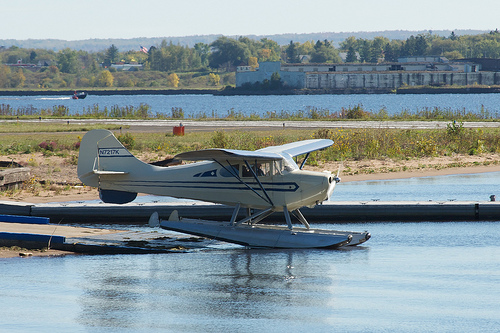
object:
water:
[0, 166, 500, 331]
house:
[230, 62, 499, 95]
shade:
[216, 240, 340, 332]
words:
[93, 145, 135, 159]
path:
[0, 115, 497, 132]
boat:
[71, 93, 88, 101]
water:
[2, 93, 499, 114]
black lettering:
[99, 149, 105, 156]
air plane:
[65, 119, 380, 259]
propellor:
[322, 154, 346, 203]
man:
[249, 160, 264, 178]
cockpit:
[240, 160, 287, 178]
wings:
[169, 137, 337, 159]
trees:
[95, 69, 114, 88]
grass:
[0, 108, 497, 192]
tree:
[164, 69, 184, 89]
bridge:
[0, 198, 498, 223]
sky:
[0, 0, 498, 41]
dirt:
[0, 192, 96, 203]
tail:
[75, 128, 144, 205]